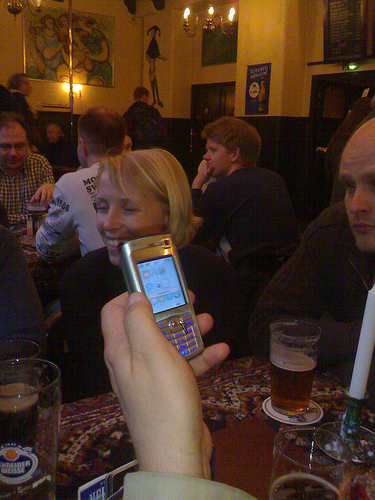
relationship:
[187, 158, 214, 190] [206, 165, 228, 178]
hand on chin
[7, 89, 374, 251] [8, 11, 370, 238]
people are in a restaurant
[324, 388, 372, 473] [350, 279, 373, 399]
holder has candle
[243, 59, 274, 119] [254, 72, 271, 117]
advertisement for beer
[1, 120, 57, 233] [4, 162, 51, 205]
man wearing plaid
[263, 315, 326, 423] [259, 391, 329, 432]
glass on coaster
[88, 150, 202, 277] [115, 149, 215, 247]
woman has blonde hair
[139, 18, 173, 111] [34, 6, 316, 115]
poster hanging on wall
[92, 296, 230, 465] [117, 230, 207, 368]
hand holding cell phone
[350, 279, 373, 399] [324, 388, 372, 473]
candle in candlestick